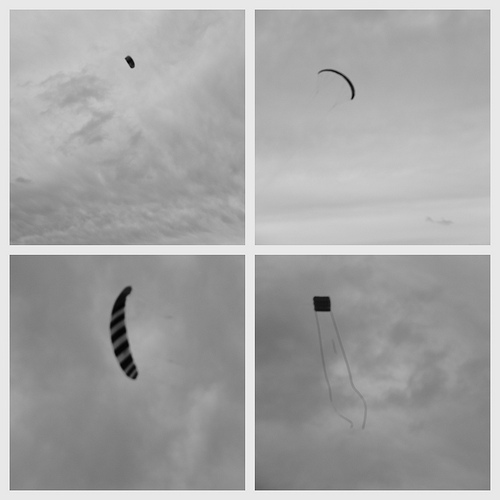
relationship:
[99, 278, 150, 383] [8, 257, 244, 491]
parasail in sky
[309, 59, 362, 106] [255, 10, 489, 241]
parasail in air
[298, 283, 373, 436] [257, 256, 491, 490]
kite in air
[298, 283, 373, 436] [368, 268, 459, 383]
kite in sky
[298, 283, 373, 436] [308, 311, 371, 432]
kite with tail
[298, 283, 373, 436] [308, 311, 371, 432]
kite has tail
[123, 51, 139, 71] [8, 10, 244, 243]
kite in sky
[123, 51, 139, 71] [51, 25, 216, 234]
kite among clouds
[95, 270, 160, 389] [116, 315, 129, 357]
kite has stripes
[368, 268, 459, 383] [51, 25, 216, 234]
sky has clouds